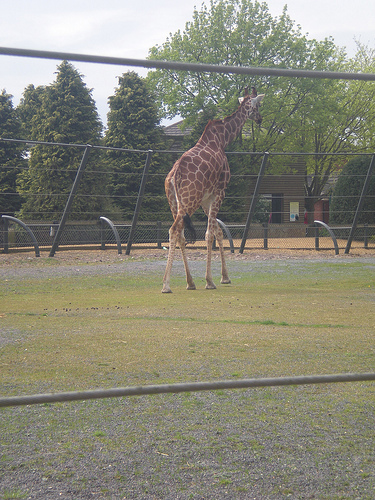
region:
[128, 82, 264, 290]
giraffe in an enclosure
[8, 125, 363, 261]
fence enclosing the giraffe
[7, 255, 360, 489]
ground giraffe walks on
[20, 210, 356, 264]
supportive structures of the fence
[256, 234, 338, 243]
ground outside the enclosure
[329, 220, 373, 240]
stone wall in front of building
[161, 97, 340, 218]
building behind the enclosure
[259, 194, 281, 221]
window on the building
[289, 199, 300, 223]
plaque on the building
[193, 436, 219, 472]
part of a ground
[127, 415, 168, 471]
a[rt of a ground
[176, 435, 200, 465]
part of a ground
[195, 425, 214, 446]
part of a ground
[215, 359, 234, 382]
partt fo post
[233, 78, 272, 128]
head of a giraffe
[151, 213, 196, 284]
leg of a giraffe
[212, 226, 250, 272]
leg of a giraffe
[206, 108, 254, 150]
neck of a giraffe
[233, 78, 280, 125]
a head of a giraffe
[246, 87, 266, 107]
an ear of a giraffe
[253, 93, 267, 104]
ear of a giraffe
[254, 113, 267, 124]
mouth of a giraffe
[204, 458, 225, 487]
part of a ground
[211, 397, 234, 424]
part of a ground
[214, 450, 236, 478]
part of a ground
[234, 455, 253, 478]
part of a ground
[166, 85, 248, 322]
this is a giraffe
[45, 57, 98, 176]
this is a tree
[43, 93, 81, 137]
the leaves are green in color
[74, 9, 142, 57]
this is the sky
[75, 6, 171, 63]
the sky is blue in color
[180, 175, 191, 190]
brown spot on the giraffe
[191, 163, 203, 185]
brown spot on the giraffe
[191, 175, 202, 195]
brown spot on the giraffe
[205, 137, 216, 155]
brown spot on the giraffe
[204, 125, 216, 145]
brown spot on the giraffe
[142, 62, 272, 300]
tall brown and tan spotted giraffe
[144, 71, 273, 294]
brown and tan spotted giraffe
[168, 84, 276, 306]
spotted giraffe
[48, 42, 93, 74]
gray pole on enclosure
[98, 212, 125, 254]
gray pole on enclosure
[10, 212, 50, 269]
gray pole on enclosure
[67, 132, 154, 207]
gray pole on enclosure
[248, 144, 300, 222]
gray pole on enclosure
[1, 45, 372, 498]
giraffe in a fenced in pen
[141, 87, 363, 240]
building outside the fence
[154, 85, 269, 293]
giraffe is walking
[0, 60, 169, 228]
evergreen trees outside the fence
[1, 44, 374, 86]
metal bar of the fence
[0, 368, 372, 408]
metal bar of the fence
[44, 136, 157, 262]
metal posts bracing the fence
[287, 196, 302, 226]
sign on the wall of the building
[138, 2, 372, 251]
Leafy trees outside the fence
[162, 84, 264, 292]
the giraffe is standing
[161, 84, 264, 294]
the giraffe has a long tail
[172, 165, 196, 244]
the black hair at the end of the tail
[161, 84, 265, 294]
the giraffe has long legs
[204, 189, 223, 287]
the leg is skinny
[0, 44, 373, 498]
the giraffe in the enclosure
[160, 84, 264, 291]
the giraffe has a short mane